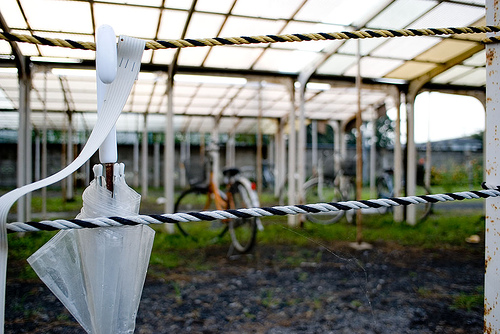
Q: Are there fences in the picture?
A: No, there are no fences.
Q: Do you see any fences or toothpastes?
A: No, there are no fences or toothpastes.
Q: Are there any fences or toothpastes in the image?
A: No, there are no fences or toothpastes.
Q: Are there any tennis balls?
A: No, there are no tennis balls.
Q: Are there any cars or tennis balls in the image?
A: No, there are no tennis balls or cars.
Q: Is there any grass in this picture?
A: Yes, there is grass.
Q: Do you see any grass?
A: Yes, there is grass.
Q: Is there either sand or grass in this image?
A: Yes, there is grass.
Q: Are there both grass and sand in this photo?
A: No, there is grass but no sand.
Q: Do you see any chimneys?
A: No, there are no chimneys.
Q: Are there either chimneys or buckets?
A: No, there are no chimneys or buckets.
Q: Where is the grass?
A: The grass is on the ground.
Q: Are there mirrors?
A: No, there are no mirrors.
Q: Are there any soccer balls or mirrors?
A: No, there are no mirrors or soccer balls.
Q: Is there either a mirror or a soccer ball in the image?
A: No, there are no mirrors or soccer balls.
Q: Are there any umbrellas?
A: Yes, there is an umbrella.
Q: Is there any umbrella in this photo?
A: Yes, there is an umbrella.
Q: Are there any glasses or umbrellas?
A: Yes, there is an umbrella.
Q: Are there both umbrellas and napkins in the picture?
A: No, there is an umbrella but no napkins.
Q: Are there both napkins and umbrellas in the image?
A: No, there is an umbrella but no napkins.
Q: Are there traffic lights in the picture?
A: No, there are no traffic lights.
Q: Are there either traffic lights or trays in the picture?
A: No, there are no traffic lights or trays.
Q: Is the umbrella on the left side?
A: Yes, the umbrella is on the left of the image.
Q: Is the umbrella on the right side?
A: No, the umbrella is on the left of the image.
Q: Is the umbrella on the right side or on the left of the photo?
A: The umbrella is on the left of the image.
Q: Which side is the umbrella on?
A: The umbrella is on the left of the image.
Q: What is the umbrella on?
A: The umbrella is on the rope.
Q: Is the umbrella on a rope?
A: Yes, the umbrella is on a rope.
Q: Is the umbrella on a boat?
A: No, the umbrella is on a rope.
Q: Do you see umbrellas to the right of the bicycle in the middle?
A: No, the umbrella is to the left of the bicycle.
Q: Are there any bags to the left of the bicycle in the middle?
A: No, there is an umbrella to the left of the bicycle.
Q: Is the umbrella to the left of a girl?
A: No, the umbrella is to the left of the bicycle.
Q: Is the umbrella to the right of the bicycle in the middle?
A: No, the umbrella is to the left of the bicycle.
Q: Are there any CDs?
A: No, there are no cds.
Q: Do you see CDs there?
A: No, there are no cds.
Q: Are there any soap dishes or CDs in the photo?
A: No, there are no CDs or soap dishes.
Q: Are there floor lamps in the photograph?
A: No, there are no floor lamps.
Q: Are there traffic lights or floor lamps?
A: No, there are no floor lamps or traffic lights.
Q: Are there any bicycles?
A: Yes, there is a bicycle.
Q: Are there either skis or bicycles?
A: Yes, there is a bicycle.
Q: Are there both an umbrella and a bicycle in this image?
A: Yes, there are both a bicycle and an umbrella.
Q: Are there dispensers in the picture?
A: No, there are no dispensers.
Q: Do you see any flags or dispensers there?
A: No, there are no dispensers or flags.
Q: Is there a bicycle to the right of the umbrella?
A: Yes, there is a bicycle to the right of the umbrella.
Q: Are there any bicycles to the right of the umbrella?
A: Yes, there is a bicycle to the right of the umbrella.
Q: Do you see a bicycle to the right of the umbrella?
A: Yes, there is a bicycle to the right of the umbrella.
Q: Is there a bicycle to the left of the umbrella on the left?
A: No, the bicycle is to the right of the umbrella.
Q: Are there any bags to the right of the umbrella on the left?
A: No, there is a bicycle to the right of the umbrella.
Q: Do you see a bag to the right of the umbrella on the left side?
A: No, there is a bicycle to the right of the umbrella.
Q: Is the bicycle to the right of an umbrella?
A: Yes, the bicycle is to the right of an umbrella.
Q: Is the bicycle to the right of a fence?
A: No, the bicycle is to the right of an umbrella.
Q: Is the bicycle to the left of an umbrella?
A: No, the bicycle is to the right of an umbrella.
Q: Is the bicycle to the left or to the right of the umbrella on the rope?
A: The bicycle is to the right of the umbrella.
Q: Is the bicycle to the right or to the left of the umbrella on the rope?
A: The bicycle is to the right of the umbrella.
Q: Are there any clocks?
A: No, there are no clocks.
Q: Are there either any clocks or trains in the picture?
A: No, there are no clocks or trains.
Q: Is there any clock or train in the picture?
A: No, there are no clocks or trains.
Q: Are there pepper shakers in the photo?
A: No, there are no pepper shakers.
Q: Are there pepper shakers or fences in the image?
A: No, there are no pepper shakers or fences.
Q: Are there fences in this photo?
A: No, there are no fences.